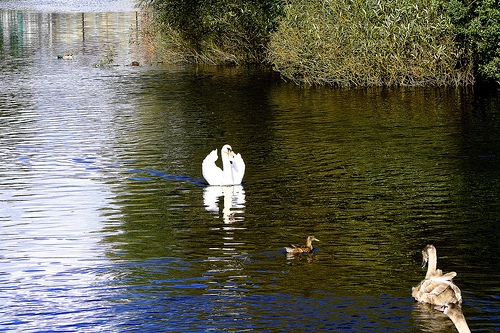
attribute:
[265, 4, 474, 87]
tree — green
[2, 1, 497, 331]
river — large